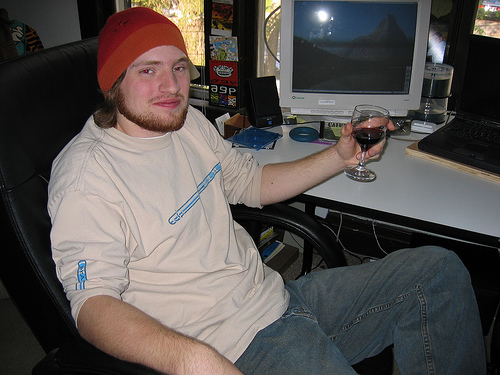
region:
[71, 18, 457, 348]
A man sitting in a chair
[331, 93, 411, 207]
A glass of wine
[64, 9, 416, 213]
A man holding a glass of wine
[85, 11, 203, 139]
A man wearing a hat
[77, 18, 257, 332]
A man wearing a white shirt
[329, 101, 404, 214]
A hand holding a glass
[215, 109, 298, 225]
A pushed up sleeve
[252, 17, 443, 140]
A white computer monitor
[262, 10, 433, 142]
A white computer monitor on a table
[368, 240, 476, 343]
The knee of a man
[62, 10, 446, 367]
man sitting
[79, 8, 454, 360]
man sitting in chair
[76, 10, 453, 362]
man holding wine glass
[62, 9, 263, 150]
man wearing red cap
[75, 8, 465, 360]
man sitting next to computer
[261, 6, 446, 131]
computer monitor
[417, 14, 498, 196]
laptop computer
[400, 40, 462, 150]
stack of CDs in case behind computer monitor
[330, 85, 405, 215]
glass of wine in persons hand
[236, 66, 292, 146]
computer speaker next to monitor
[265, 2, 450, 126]
Computer monitor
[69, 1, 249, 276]
Male wearing a red stocking hat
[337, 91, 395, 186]
Wind glass with red beverage in it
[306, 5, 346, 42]
Reflection of camera flash on computer monitor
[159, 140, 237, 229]
Blue design on white long sleeve t-shirt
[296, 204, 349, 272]
Black arm rest on computer chair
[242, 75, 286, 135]
Black computer speaker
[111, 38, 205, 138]
Man with facial hair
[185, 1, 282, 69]
Wall with a window on both sides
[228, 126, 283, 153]
Blue plastic cd case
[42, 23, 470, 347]
young man sitting in front of computer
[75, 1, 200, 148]
man with orange cap on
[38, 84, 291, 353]
man in beige t-shirt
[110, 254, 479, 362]
man wearing dirty blue jeans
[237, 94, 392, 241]
man holding wine glass with dark red liquid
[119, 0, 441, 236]
man sitting by computer screen not turned on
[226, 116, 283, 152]
small cd case on white table top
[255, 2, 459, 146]
computer screen not turned on has reflection of mountains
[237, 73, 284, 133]
small black computer speaker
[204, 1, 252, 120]
colorful stickers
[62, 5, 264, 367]
Very comfortable relaxing camera.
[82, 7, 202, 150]
Beard mustache facial hair.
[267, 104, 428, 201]
Hand holds glass red wine.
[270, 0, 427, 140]
Passe large computer monitor.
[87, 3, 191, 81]
Red knitted cap covers forehead.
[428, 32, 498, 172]
Black Laptop computer desk.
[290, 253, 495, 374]
Faded ripped blue jean leg.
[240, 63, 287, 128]
Small speaker music sound.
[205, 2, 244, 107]
Brochure tacked window wall.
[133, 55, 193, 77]
Red eyed camera flash.